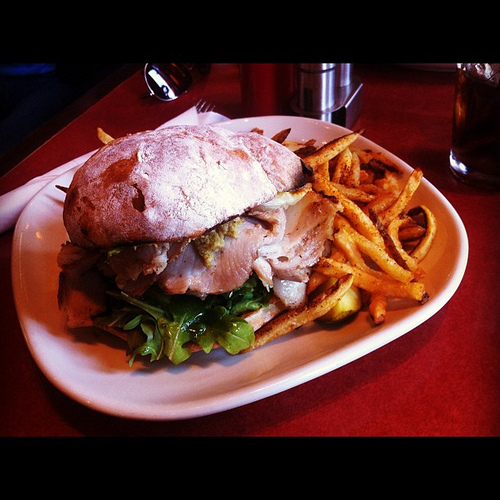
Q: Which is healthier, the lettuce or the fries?
A: The lettuce is healthier than the fries.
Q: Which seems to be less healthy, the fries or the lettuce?
A: The fries is less healthy than the lettuce.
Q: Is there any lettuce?
A: Yes, there is lettuce.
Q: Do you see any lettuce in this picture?
A: Yes, there is lettuce.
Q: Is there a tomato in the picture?
A: No, there are no tomatoes.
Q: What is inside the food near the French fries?
A: The lettuce is inside the sandwich.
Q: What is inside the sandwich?
A: The lettuce is inside the sandwich.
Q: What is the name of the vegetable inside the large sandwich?
A: The vegetable is lettuce.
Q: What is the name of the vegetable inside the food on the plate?
A: The vegetable is lettuce.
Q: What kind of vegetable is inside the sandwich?
A: The vegetable is lettuce.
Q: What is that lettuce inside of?
A: The lettuce is inside the sandwich.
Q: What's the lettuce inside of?
A: The lettuce is inside the sandwich.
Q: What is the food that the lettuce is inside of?
A: The food is a sandwich.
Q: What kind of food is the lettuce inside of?
A: The lettuce is inside the sandwich.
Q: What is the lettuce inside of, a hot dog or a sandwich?
A: The lettuce is inside a sandwich.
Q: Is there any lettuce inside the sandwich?
A: Yes, there is lettuce inside the sandwich.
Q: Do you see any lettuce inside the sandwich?
A: Yes, there is lettuce inside the sandwich.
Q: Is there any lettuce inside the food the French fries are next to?
A: Yes, there is lettuce inside the sandwich.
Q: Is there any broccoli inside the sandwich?
A: No, there is lettuce inside the sandwich.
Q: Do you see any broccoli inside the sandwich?
A: No, there is lettuce inside the sandwich.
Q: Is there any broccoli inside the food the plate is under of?
A: No, there is lettuce inside the sandwich.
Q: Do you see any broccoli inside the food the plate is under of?
A: No, there is lettuce inside the sandwich.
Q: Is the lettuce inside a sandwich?
A: Yes, the lettuce is inside a sandwich.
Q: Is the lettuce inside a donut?
A: No, the lettuce is inside a sandwich.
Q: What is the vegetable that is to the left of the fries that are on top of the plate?
A: The vegetable is lettuce.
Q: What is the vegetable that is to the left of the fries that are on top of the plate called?
A: The vegetable is lettuce.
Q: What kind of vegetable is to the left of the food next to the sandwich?
A: The vegetable is lettuce.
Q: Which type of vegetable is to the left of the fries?
A: The vegetable is lettuce.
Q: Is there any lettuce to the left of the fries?
A: Yes, there is lettuce to the left of the fries.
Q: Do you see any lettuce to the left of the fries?
A: Yes, there is lettuce to the left of the fries.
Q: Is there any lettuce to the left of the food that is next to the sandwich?
A: Yes, there is lettuce to the left of the fries.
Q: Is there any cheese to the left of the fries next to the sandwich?
A: No, there is lettuce to the left of the French fries.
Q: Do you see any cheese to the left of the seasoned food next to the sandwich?
A: No, there is lettuce to the left of the French fries.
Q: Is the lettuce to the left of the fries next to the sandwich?
A: Yes, the lettuce is to the left of the fries.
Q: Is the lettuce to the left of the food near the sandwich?
A: Yes, the lettuce is to the left of the fries.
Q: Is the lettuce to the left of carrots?
A: No, the lettuce is to the left of the fries.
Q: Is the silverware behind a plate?
A: Yes, the silverware is behind a plate.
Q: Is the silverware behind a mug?
A: No, the silverware is behind a plate.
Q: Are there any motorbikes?
A: No, there are no motorbikes.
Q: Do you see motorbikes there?
A: No, there are no motorbikes.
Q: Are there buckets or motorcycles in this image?
A: No, there are no motorcycles or buckets.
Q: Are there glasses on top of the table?
A: Yes, there are glasses on top of the table.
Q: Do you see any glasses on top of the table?
A: Yes, there are glasses on top of the table.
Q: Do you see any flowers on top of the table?
A: No, there are glasses on top of the table.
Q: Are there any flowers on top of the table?
A: No, there are glasses on top of the table.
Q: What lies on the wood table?
A: The glasses lie on the table.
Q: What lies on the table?
A: The glasses lie on the table.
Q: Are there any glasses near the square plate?
A: Yes, there are glasses near the plate.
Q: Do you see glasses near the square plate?
A: Yes, there are glasses near the plate.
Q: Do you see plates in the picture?
A: Yes, there is a plate.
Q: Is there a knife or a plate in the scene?
A: Yes, there is a plate.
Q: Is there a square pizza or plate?
A: Yes, there is a square plate.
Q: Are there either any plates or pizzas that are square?
A: Yes, the plate is square.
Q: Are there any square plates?
A: Yes, there is a square plate.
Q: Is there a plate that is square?
A: Yes, there is a plate that is square.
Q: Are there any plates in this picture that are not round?
A: Yes, there is a square plate.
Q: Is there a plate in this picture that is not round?
A: Yes, there is a square plate.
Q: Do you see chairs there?
A: No, there are no chairs.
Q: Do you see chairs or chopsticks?
A: No, there are no chairs or chopsticks.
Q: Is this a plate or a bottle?
A: This is a plate.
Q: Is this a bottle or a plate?
A: This is a plate.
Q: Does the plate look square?
A: Yes, the plate is square.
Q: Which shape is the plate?
A: The plate is square.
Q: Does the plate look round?
A: No, the plate is square.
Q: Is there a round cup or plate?
A: No, there is a plate but it is square.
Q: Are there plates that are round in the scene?
A: No, there is a plate but it is square.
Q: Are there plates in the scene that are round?
A: No, there is a plate but it is square.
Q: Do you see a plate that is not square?
A: No, there is a plate but it is square.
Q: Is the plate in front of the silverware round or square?
A: The plate is square.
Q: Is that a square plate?
A: Yes, that is a square plate.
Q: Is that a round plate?
A: No, that is a square plate.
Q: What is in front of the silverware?
A: The plate is in front of the silverware.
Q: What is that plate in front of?
A: The plate is in front of the silverware.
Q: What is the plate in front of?
A: The plate is in front of the silverware.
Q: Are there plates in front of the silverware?
A: Yes, there is a plate in front of the silverware.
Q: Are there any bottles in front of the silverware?
A: No, there is a plate in front of the silverware.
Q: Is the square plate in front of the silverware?
A: Yes, the plate is in front of the silverware.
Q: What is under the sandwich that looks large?
A: The plate is under the sandwich.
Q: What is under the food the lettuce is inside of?
A: The plate is under the sandwich.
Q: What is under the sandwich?
A: The plate is under the sandwich.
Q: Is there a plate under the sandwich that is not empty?
A: Yes, there is a plate under the sandwich.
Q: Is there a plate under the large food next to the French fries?
A: Yes, there is a plate under the sandwich.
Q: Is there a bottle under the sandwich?
A: No, there is a plate under the sandwich.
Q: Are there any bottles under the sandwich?
A: No, there is a plate under the sandwich.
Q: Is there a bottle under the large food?
A: No, there is a plate under the sandwich.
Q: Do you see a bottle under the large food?
A: No, there is a plate under the sandwich.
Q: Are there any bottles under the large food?
A: No, there is a plate under the sandwich.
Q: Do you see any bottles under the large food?
A: No, there is a plate under the sandwich.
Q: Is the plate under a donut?
A: No, the plate is under the sandwich.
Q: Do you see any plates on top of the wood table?
A: Yes, there is a plate on top of the table.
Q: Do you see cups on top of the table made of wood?
A: No, there is a plate on top of the table.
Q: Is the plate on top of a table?
A: Yes, the plate is on top of a table.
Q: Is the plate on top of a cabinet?
A: No, the plate is on top of a table.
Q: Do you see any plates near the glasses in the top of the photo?
A: Yes, there is a plate near the glasses.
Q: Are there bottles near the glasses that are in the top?
A: No, there is a plate near the glasses.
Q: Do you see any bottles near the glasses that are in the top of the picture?
A: No, there is a plate near the glasses.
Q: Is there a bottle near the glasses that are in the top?
A: No, there is a plate near the glasses.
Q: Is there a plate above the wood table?
A: Yes, there is a plate above the table.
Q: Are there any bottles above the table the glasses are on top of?
A: No, there is a plate above the table.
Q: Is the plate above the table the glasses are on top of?
A: Yes, the plate is above the table.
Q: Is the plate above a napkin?
A: No, the plate is above the table.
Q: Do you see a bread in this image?
A: Yes, there is a bread.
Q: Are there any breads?
A: Yes, there is a bread.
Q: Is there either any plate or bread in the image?
A: Yes, there is a bread.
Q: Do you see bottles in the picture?
A: No, there are no bottles.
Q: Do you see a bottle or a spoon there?
A: No, there are no bottles or spoons.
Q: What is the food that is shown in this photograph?
A: The food is a bread.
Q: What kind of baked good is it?
A: The food is a bread.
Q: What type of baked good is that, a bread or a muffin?
A: That is a bread.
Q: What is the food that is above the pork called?
A: The food is a bread.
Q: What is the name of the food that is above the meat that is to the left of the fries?
A: The food is a bread.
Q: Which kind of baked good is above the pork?
A: The food is a bread.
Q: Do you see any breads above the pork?
A: Yes, there is a bread above the pork.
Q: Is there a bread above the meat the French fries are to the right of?
A: Yes, there is a bread above the pork.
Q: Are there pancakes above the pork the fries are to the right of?
A: No, there is a bread above the pork.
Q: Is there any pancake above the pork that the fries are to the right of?
A: No, there is a bread above the pork.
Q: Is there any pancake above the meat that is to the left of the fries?
A: No, there is a bread above the pork.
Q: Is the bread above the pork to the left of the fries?
A: Yes, the bread is above the pork.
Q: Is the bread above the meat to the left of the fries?
A: Yes, the bread is above the pork.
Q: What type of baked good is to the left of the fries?
A: The food is a bread.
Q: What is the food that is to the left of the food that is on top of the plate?
A: The food is a bread.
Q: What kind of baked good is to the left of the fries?
A: The food is a bread.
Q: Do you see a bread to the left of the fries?
A: Yes, there is a bread to the left of the fries.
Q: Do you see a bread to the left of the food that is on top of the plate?
A: Yes, there is a bread to the left of the fries.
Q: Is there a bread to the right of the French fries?
A: No, the bread is to the left of the French fries.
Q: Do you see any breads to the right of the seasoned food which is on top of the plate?
A: No, the bread is to the left of the French fries.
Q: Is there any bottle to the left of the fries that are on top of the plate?
A: No, there is a bread to the left of the French fries.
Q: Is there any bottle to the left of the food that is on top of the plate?
A: No, there is a bread to the left of the French fries.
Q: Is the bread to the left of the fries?
A: Yes, the bread is to the left of the fries.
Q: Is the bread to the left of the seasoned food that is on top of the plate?
A: Yes, the bread is to the left of the fries.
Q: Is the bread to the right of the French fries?
A: No, the bread is to the left of the French fries.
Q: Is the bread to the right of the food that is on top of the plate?
A: No, the bread is to the left of the French fries.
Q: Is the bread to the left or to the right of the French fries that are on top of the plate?
A: The bread is to the left of the fries.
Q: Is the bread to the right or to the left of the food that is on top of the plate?
A: The bread is to the left of the fries.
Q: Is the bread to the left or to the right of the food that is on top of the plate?
A: The bread is to the left of the fries.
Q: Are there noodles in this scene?
A: No, there are no noodles.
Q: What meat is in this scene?
A: The meat is pork.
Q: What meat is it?
A: The meat is pork.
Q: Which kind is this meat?
A: This is pork.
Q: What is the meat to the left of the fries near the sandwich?
A: The meat is pork.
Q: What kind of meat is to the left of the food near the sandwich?
A: The meat is pork.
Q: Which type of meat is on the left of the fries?
A: The meat is pork.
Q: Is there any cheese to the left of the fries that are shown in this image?
A: No, there is pork to the left of the fries.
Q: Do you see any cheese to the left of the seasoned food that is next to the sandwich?
A: No, there is pork to the left of the fries.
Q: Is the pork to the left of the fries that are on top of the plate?
A: Yes, the pork is to the left of the fries.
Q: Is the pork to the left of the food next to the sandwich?
A: Yes, the pork is to the left of the fries.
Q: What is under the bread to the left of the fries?
A: The pork is under the bread.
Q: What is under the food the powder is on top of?
A: The pork is under the bread.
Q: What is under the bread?
A: The pork is under the bread.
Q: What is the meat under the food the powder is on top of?
A: The meat is pork.